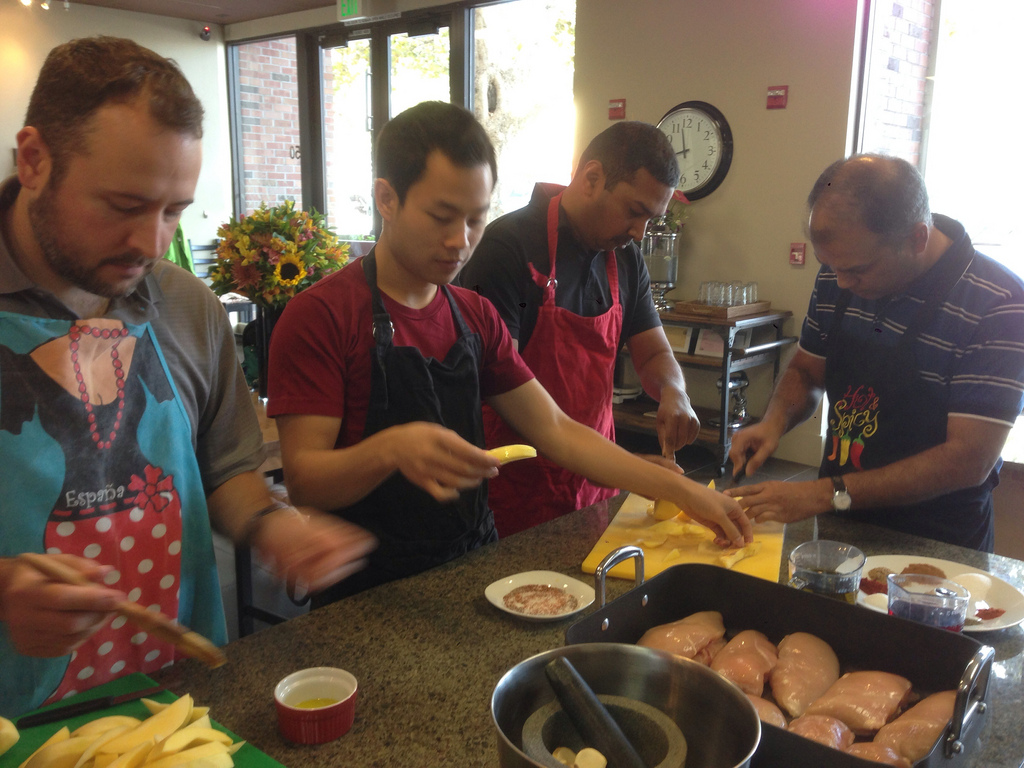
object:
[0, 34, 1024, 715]
men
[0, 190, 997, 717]
aprons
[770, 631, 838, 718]
piece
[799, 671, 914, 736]
meat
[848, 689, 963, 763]
meat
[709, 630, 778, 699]
meat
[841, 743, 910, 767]
meat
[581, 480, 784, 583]
board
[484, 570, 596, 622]
plate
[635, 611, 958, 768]
chicken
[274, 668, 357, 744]
cup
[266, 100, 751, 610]
man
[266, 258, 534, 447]
t-shirt